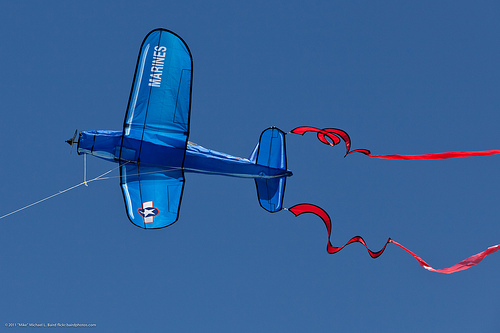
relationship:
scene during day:
[2, 6, 499, 323] [6, 4, 495, 327]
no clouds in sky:
[3, 5, 496, 312] [9, 8, 495, 327]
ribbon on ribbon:
[283, 125, 499, 275] [283, 125, 499, 275]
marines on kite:
[145, 42, 168, 92] [145, 43, 169, 90]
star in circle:
[139, 205, 159, 218] [138, 205, 159, 218]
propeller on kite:
[62, 127, 79, 148] [64, 127, 81, 150]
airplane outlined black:
[62, 27, 499, 276] [60, 26, 294, 231]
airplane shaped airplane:
[62, 27, 499, 276] [62, 27, 499, 276]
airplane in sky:
[62, 27, 499, 276] [64, 25, 499, 278]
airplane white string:
[62, 27, 499, 276] [3, 152, 181, 221]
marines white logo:
[145, 42, 168, 92] [146, 42, 168, 90]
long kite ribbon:
[286, 120, 499, 277] [283, 125, 499, 275]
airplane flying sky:
[62, 23, 498, 292] [60, 16, 498, 309]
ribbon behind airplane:
[288, 120, 498, 278] [284, 117, 499, 278]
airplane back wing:
[62, 27, 499, 276] [250, 123, 295, 218]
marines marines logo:
[147, 45, 167, 88] [146, 42, 168, 90]